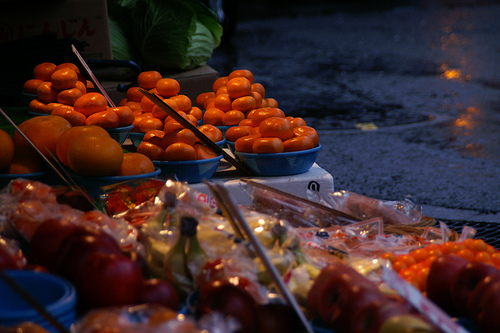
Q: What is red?
A: Tomato.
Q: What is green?
A: Lettuce.